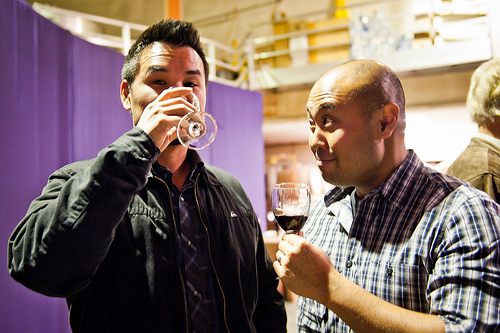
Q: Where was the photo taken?
A: It was taken at the walkway.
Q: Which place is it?
A: It is a walkway.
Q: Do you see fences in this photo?
A: No, there are no fences.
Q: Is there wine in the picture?
A: Yes, there is wine.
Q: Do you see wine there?
A: Yes, there is wine.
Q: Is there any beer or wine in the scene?
A: Yes, there is wine.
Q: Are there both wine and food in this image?
A: No, there is wine but no food.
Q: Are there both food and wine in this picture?
A: No, there is wine but no food.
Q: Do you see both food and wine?
A: No, there is wine but no food.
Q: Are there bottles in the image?
A: No, there are no bottles.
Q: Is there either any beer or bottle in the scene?
A: No, there are no bottles or beer.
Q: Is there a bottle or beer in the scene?
A: No, there are no bottles or beer.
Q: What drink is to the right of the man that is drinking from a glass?
A: The drink is wine.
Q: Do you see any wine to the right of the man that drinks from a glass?
A: Yes, there is wine to the right of the man.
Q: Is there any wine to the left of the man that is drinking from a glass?
A: No, the wine is to the right of the man.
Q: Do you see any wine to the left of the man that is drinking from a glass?
A: No, the wine is to the right of the man.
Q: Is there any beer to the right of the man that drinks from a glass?
A: No, there is wine to the right of the man.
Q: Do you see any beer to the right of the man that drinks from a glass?
A: No, there is wine to the right of the man.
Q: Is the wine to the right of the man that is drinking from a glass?
A: Yes, the wine is to the right of the man.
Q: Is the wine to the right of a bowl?
A: No, the wine is to the right of the man.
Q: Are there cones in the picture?
A: No, there are no cones.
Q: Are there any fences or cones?
A: No, there are no cones or fences.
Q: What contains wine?
A: The glass contains wine.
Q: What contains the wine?
A: The glass contains wine.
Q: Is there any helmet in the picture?
A: No, there are no helmets.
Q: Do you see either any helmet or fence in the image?
A: No, there are no helmets or fences.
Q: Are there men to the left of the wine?
A: Yes, there is a man to the left of the wine.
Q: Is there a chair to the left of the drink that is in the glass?
A: No, there is a man to the left of the wine.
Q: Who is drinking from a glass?
A: The man is drinking from a glass.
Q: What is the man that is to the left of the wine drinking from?
A: The man is drinking from a glass.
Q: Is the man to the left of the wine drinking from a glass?
A: Yes, the man is drinking from a glass.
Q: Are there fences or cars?
A: No, there are no cars or fences.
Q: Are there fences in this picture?
A: No, there are no fences.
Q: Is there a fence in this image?
A: No, there are no fences.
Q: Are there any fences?
A: No, there are no fences.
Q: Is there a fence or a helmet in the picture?
A: No, there are no fences or helmets.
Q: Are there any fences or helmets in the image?
A: No, there are no fences or helmets.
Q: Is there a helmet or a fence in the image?
A: No, there are no fences or helmets.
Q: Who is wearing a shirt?
A: The man is wearing a shirt.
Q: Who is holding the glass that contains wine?
A: The man is holding the glass.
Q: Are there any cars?
A: No, there are no cars.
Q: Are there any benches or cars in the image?
A: No, there are no cars or benches.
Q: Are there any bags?
A: No, there are no bags.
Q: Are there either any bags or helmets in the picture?
A: No, there are no bags or helmets.